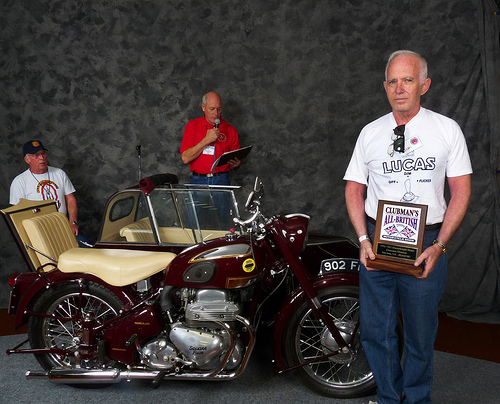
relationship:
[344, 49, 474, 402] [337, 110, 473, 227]
man with shirt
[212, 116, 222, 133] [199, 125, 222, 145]
microphone in hand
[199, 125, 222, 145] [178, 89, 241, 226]
hand of man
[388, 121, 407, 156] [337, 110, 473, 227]
glasses hanging on shirt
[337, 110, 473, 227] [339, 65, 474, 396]
shirt of person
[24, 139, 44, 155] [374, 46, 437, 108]
cap on head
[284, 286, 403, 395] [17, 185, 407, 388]
front wheel of motorcycle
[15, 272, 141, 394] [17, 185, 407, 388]
wheel on motorcycle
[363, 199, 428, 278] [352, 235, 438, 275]
board in hands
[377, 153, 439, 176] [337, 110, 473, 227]
letters on shirt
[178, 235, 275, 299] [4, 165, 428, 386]
tank on motorcycle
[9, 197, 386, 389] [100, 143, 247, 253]
motorcycle and side car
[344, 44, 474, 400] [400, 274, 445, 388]
man standing with leg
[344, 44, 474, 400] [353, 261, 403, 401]
man standing with leg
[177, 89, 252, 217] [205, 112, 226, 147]
man holding microphone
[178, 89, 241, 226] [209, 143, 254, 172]
man holding clipboard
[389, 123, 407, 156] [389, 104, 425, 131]
glasses hung from collar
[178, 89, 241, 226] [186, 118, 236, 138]
man with microphone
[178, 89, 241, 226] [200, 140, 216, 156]
man wearing tag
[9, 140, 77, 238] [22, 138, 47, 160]
man wearing cap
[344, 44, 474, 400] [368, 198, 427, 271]
man holding plaque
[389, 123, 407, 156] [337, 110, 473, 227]
glasses on shirt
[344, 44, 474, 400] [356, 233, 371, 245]
man wearing watch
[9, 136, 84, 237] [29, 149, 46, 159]
man wearing eyeglasses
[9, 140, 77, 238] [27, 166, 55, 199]
man wearing necklace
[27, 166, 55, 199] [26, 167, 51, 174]
necklace around neck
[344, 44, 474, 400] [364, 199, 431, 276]
man holding plaque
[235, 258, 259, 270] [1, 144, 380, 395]
sticker on motorcycle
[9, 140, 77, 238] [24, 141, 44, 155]
man wearing cap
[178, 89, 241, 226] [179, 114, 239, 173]
man wearing shirt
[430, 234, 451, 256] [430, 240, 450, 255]
watch on wrist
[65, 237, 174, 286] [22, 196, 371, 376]
seat of motorcycle